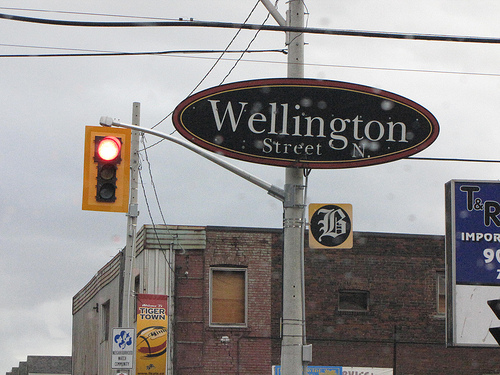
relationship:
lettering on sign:
[209, 94, 416, 156] [176, 76, 446, 169]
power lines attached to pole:
[2, 3, 483, 58] [282, 1, 310, 371]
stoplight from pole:
[77, 121, 136, 218] [268, 0, 312, 372]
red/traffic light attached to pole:
[95, 134, 126, 163] [281, 3, 308, 373]